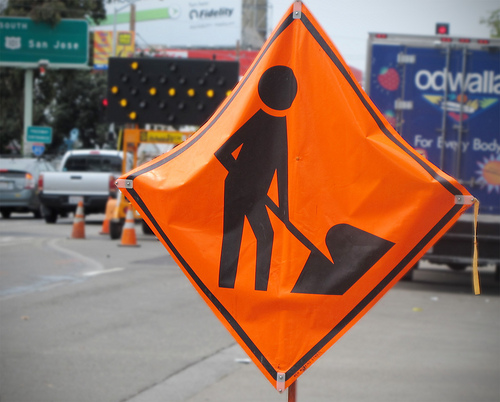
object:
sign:
[118, 1, 477, 392]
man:
[214, 66, 298, 292]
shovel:
[268, 199, 396, 296]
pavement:
[5, 216, 499, 400]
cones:
[68, 197, 89, 240]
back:
[38, 167, 116, 204]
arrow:
[111, 61, 232, 118]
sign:
[2, 16, 89, 68]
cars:
[38, 148, 124, 222]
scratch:
[116, 343, 261, 397]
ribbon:
[468, 195, 486, 295]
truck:
[365, 33, 499, 283]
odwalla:
[413, 69, 499, 95]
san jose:
[28, 38, 80, 52]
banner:
[91, 3, 272, 47]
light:
[434, 23, 452, 33]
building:
[132, 38, 383, 181]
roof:
[150, 48, 254, 78]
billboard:
[88, 25, 134, 71]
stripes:
[69, 202, 137, 227]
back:
[371, 44, 498, 213]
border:
[128, 15, 465, 378]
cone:
[118, 201, 142, 245]